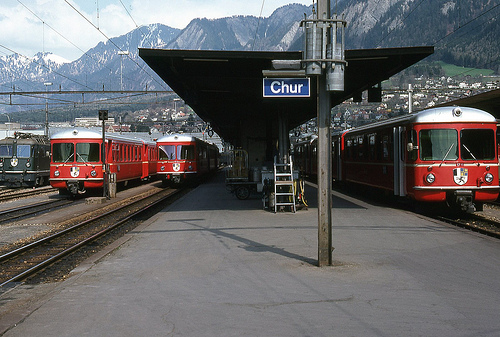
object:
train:
[297, 104, 500, 206]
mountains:
[332, 0, 500, 121]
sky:
[4, 1, 312, 63]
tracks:
[404, 196, 500, 242]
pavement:
[5, 179, 500, 336]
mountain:
[2, 49, 158, 112]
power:
[0, 51, 171, 104]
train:
[50, 128, 157, 198]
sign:
[259, 73, 311, 98]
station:
[1, 156, 497, 337]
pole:
[315, 50, 336, 265]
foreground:
[7, 169, 500, 337]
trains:
[156, 131, 221, 185]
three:
[49, 105, 500, 203]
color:
[59, 243, 84, 264]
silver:
[50, 128, 222, 144]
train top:
[56, 124, 158, 142]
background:
[3, 0, 500, 336]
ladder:
[274, 153, 296, 217]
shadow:
[126, 211, 459, 268]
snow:
[0, 48, 75, 81]